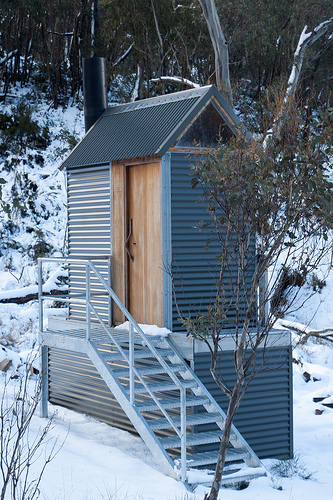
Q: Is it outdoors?
A: Yes, it is outdoors.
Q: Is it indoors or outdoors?
A: It is outdoors.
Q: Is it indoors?
A: No, it is outdoors.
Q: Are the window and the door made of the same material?
A: No, the window is made of glass and the door is made of wood.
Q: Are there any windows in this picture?
A: Yes, there is a window.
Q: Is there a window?
A: Yes, there is a window.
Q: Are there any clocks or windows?
A: Yes, there is a window.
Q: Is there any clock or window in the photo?
A: Yes, there is a window.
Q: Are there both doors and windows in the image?
A: Yes, there are both a window and a door.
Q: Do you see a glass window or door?
A: Yes, there is a glass window.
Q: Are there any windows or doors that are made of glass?
A: Yes, the window is made of glass.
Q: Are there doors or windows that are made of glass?
A: Yes, the window is made of glass.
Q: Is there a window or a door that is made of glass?
A: Yes, the window is made of glass.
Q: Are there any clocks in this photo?
A: No, there are no clocks.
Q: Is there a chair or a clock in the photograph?
A: No, there are no clocks or chairs.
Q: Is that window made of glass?
A: Yes, the window is made of glass.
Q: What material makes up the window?
A: The window is made of glass.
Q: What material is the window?
A: The window is made of glass.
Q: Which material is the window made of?
A: The window is made of glass.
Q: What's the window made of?
A: The window is made of glass.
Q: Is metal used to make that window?
A: No, the window is made of glass.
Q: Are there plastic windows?
A: No, there is a window but it is made of glass.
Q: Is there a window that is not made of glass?
A: No, there is a window but it is made of glass.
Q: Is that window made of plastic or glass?
A: The window is made of glass.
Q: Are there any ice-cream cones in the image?
A: No, there are no ice-cream cones.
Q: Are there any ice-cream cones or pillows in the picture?
A: No, there are no ice-cream cones or pillows.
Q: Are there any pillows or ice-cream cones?
A: No, there are no ice-cream cones or pillows.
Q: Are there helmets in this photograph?
A: No, there are no helmets.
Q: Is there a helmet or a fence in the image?
A: No, there are no helmets or fences.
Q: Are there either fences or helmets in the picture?
A: No, there are no helmets or fences.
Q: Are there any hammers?
A: No, there are no hammers.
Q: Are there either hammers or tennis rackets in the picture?
A: No, there are no hammers or tennis rackets.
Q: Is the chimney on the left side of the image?
A: Yes, the chimney is on the left of the image.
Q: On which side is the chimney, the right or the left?
A: The chimney is on the left of the image.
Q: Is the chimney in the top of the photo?
A: Yes, the chimney is in the top of the image.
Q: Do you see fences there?
A: No, there are no fences.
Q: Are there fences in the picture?
A: No, there are no fences.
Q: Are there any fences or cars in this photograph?
A: No, there are no fences or cars.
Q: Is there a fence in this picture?
A: No, there are no fences.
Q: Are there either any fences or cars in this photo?
A: No, there are no fences or cars.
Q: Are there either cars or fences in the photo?
A: No, there are no fences or cars.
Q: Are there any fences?
A: No, there are no fences.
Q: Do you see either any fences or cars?
A: No, there are no fences or cars.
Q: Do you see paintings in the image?
A: No, there are no paintings.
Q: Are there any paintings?
A: No, there are no paintings.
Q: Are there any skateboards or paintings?
A: No, there are no paintings or skateboards.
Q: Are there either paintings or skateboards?
A: No, there are no paintings or skateboards.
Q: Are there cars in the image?
A: No, there are no cars.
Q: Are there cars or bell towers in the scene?
A: No, there are no cars or bell towers.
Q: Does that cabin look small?
A: Yes, the cabin is small.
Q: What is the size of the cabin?
A: The cabin is small.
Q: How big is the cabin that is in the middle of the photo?
A: The cabin is small.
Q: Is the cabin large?
A: No, the cabin is small.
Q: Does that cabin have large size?
A: No, the cabin is small.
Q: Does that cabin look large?
A: No, the cabin is small.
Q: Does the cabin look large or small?
A: The cabin is small.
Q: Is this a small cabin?
A: Yes, this is a small cabin.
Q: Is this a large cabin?
A: No, this is a small cabin.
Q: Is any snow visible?
A: Yes, there is snow.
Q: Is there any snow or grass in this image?
A: Yes, there is snow.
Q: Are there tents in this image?
A: No, there are no tents.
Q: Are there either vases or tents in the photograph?
A: No, there are no tents or vases.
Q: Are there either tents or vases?
A: No, there are no tents or vases.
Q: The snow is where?
A: The snow is on the ground.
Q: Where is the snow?
A: The snow is on the ground.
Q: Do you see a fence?
A: No, there are no fences.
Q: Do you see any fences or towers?
A: No, there are no fences or towers.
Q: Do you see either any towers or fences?
A: No, there are no fences or towers.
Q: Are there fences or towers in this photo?
A: No, there are no fences or towers.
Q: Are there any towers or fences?
A: No, there are no fences or towers.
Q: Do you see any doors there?
A: Yes, there is a door.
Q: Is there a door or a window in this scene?
A: Yes, there is a door.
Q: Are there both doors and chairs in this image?
A: No, there is a door but no chairs.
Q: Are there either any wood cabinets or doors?
A: Yes, there is a wood door.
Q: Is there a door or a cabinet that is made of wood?
A: Yes, the door is made of wood.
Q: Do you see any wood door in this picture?
A: Yes, there is a wood door.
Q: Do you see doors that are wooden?
A: Yes, there is a door that is wooden.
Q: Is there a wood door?
A: Yes, there is a door that is made of wood.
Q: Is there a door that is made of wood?
A: Yes, there is a door that is made of wood.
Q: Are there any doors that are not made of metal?
A: Yes, there is a door that is made of wood.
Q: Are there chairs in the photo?
A: No, there are no chairs.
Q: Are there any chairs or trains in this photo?
A: No, there are no chairs or trains.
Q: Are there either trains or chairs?
A: No, there are no chairs or trains.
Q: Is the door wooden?
A: Yes, the door is wooden.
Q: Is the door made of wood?
A: Yes, the door is made of wood.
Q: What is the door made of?
A: The door is made of wood.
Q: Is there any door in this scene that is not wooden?
A: No, there is a door but it is wooden.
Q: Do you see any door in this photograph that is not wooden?
A: No, there is a door but it is wooden.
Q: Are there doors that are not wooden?
A: No, there is a door but it is wooden.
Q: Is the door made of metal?
A: No, the door is made of wood.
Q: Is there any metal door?
A: No, there is a door but it is made of wood.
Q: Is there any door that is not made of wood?
A: No, there is a door but it is made of wood.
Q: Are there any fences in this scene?
A: No, there are no fences.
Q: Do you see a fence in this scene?
A: No, there are no fences.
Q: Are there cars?
A: No, there are no cars.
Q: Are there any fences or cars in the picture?
A: No, there are no cars or fences.